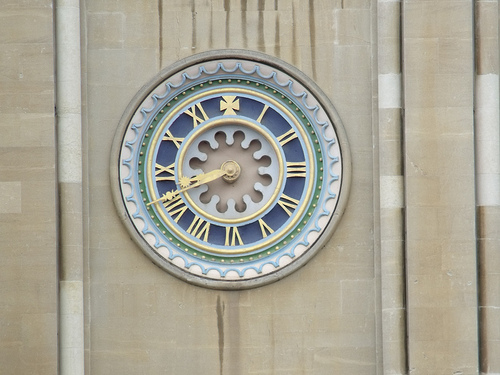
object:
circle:
[108, 48, 353, 290]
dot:
[246, 80, 250, 85]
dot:
[310, 130, 315, 135]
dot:
[315, 193, 320, 199]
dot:
[274, 245, 281, 251]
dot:
[156, 223, 161, 228]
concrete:
[55, 0, 84, 374]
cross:
[219, 95, 240, 116]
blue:
[155, 95, 307, 246]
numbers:
[224, 226, 245, 246]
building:
[0, 0, 499, 373]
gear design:
[181, 123, 279, 221]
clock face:
[137, 80, 324, 266]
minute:
[145, 162, 238, 206]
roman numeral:
[183, 102, 210, 129]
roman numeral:
[256, 104, 271, 123]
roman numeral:
[275, 128, 298, 147]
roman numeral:
[286, 161, 307, 178]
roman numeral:
[277, 192, 301, 217]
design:
[118, 58, 343, 281]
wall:
[0, 0, 500, 375]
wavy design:
[157, 0, 319, 82]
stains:
[153, 0, 318, 83]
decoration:
[122, 62, 340, 278]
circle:
[145, 87, 315, 256]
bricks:
[59, 244, 84, 282]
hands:
[175, 163, 238, 188]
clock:
[106, 48, 353, 290]